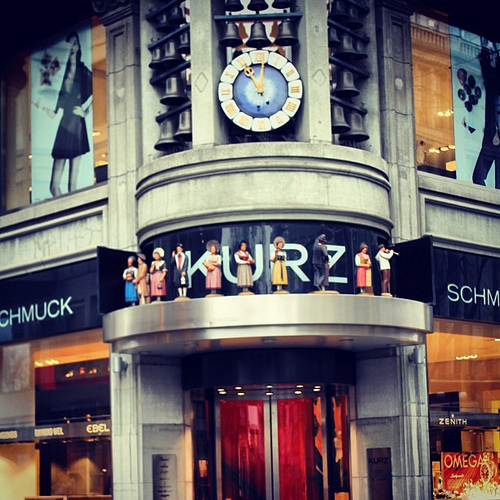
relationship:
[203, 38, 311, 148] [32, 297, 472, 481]
clock on building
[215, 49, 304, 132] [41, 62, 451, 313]
clock on building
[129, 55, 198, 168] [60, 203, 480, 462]
bells on building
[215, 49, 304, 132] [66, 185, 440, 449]
clock on building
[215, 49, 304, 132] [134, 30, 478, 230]
clock on building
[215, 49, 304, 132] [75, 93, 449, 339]
clock on building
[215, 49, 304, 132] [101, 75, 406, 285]
clock on building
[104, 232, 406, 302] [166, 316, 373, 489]
statues on door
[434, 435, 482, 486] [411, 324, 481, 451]
perfume in window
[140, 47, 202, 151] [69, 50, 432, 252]
bells on building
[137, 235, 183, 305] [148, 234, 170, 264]
statue wearing hat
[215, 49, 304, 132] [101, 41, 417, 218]
clock on building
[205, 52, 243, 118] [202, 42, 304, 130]
numbers on clock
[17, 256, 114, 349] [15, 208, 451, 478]
sign on building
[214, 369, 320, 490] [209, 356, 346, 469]
curtains on entrance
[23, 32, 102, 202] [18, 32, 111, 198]
picture on window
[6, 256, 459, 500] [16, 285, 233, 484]
picture on window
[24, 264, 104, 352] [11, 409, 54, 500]
writing on side of wall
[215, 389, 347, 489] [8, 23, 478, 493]
door on store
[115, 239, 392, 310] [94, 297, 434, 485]
figurines on entrance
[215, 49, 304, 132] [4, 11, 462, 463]
clock on building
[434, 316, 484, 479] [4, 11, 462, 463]
window on building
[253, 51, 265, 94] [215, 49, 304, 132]
clock hand on clock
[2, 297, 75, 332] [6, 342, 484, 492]
logo's on window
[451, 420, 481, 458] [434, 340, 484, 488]
woman in window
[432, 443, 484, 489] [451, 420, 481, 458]
poster of woman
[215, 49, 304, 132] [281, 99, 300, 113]
clock has numerals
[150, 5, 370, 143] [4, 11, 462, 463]
bells on building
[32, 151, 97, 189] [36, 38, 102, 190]
legs on woman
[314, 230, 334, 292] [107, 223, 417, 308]
figurine on awing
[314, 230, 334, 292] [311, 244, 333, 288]
figurine wearing coat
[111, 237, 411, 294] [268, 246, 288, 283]
awing wearing dress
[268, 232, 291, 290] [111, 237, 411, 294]
figurine on awing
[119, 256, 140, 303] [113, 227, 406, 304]
figurine on awing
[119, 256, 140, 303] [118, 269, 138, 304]
figurine wearing dress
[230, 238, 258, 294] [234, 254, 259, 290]
figurine wearing dress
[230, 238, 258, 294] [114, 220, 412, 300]
figurine on awing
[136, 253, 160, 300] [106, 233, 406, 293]
figurine on awing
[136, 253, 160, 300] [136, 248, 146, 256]
figurine wearing fedora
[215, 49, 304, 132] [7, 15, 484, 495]
clock on building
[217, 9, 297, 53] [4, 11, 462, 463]
toys on building